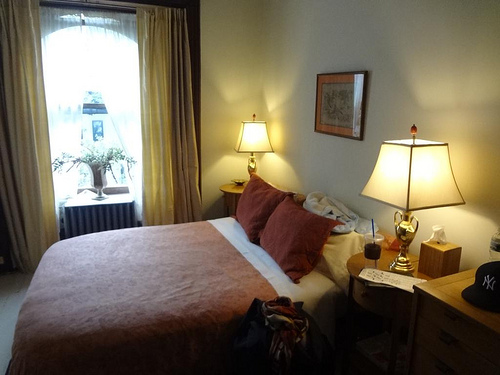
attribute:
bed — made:
[68, 173, 372, 356]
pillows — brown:
[234, 174, 335, 273]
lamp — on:
[359, 95, 441, 278]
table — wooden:
[347, 244, 419, 354]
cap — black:
[461, 263, 498, 315]